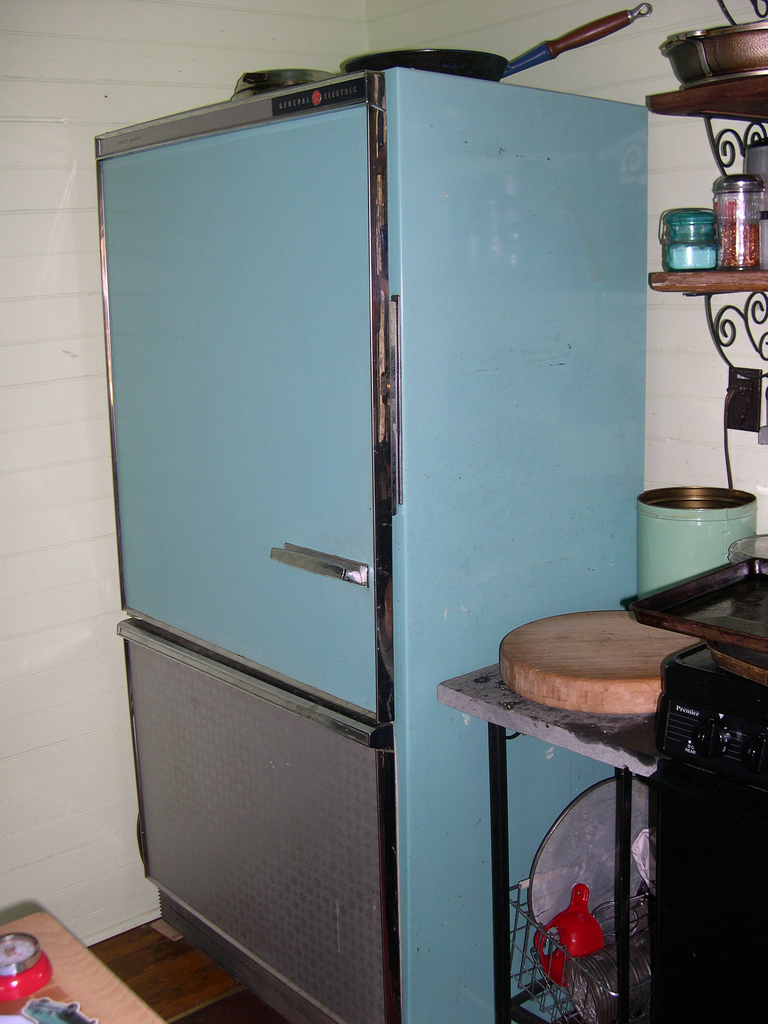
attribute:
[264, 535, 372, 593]
handle — metal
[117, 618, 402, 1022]
freezer — gray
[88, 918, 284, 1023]
floor — wooden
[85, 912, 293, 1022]
floor — brown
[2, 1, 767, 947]
wall — tiled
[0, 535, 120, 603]
tile — white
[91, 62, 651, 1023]
fridge — white, large